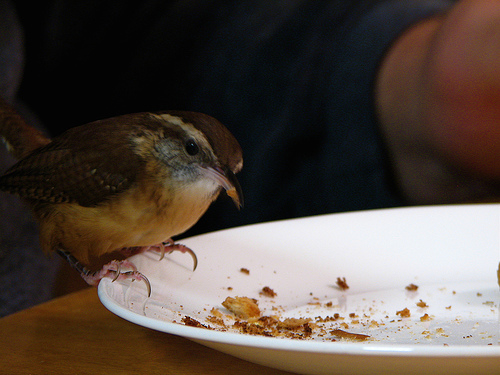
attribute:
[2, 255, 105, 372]
tabletop — brown 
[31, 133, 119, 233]
feathers — brown 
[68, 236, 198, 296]
feet — gray 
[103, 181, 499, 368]
plate — White 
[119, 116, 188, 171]
feathers — Grey 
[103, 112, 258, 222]
beak — black 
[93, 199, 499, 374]
plate — white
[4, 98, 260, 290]
bird — Yellow 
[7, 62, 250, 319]
bird — EATING 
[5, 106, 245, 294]
bird — LITTLE , small